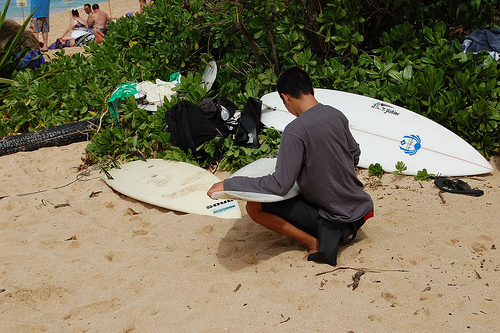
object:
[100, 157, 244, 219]
surfboard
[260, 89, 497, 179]
surfboard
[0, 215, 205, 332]
sand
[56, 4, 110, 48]
people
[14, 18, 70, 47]
beach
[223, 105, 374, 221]
shirt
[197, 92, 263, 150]
wetsuit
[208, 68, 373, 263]
man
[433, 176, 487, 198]
strap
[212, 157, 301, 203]
board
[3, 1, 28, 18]
water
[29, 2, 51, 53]
man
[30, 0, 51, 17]
shirt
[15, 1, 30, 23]
sign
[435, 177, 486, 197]
slipper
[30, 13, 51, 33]
shorts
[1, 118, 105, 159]
log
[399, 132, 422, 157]
sticker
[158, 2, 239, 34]
bushes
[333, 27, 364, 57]
leaves